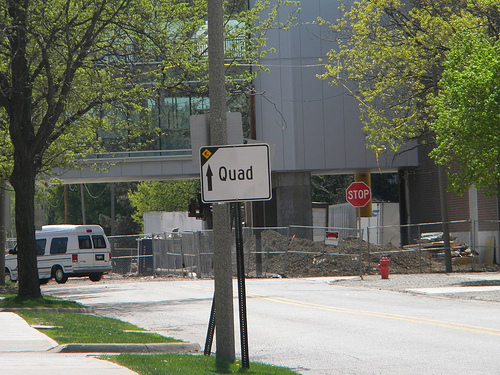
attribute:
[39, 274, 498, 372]
street — grey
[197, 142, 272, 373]
direction sign — black, white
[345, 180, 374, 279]
stop sign — red, white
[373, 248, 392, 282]
hydrant — red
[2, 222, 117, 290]
van — white, parked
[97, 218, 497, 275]
fence — chain link, metal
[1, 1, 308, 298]
tree — green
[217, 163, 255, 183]
quad — direction sign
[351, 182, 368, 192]
red — stop sign